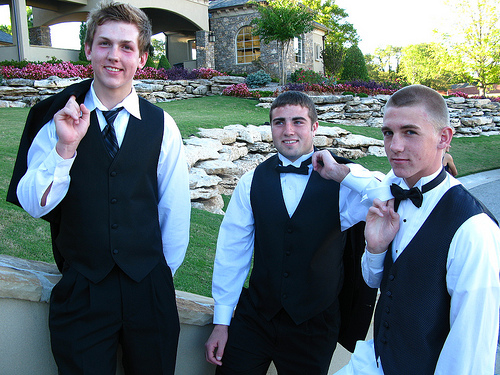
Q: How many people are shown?
A: Three.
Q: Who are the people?
A: Boys.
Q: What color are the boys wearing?
A: Black and white.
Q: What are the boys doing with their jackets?
A: Hanging them over their shoulders.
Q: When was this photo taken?
A: Daytime.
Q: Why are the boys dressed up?
A: A special occasion.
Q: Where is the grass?
A: Behind the boys.